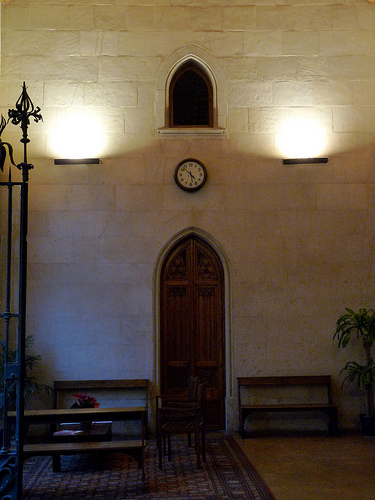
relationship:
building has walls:
[1, 1, 374, 498] [9, 4, 375, 431]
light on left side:
[39, 94, 114, 170] [3, 1, 200, 499]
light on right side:
[270, 114, 331, 161] [197, 3, 368, 496]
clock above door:
[171, 157, 215, 193] [157, 230, 229, 432]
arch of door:
[152, 223, 225, 261] [157, 230, 229, 432]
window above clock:
[159, 53, 220, 130] [171, 157, 215, 193]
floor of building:
[252, 428, 374, 498] [1, 1, 374, 498]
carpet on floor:
[3, 417, 266, 499] [252, 428, 374, 498]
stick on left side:
[10, 76, 40, 499] [3, 1, 200, 499]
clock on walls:
[171, 157, 215, 193] [9, 4, 375, 431]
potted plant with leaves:
[324, 308, 375, 441] [332, 304, 375, 396]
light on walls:
[39, 94, 114, 170] [9, 4, 375, 431]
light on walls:
[270, 114, 331, 161] [9, 4, 375, 431]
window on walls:
[159, 53, 220, 130] [9, 4, 375, 431]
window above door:
[159, 53, 220, 130] [157, 230, 229, 432]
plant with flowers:
[70, 391, 102, 430] [66, 391, 101, 408]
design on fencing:
[1, 83, 48, 180] [1, 80, 29, 499]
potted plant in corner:
[324, 308, 375, 441] [328, 2, 375, 499]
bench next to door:
[234, 372, 339, 432] [157, 230, 229, 432]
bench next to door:
[46, 375, 153, 440] [157, 230, 229, 432]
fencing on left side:
[1, 80, 29, 499] [3, 1, 200, 499]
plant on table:
[70, 391, 102, 430] [49, 409, 115, 458]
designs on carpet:
[14, 442, 238, 499] [3, 417, 266, 499]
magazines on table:
[60, 418, 110, 436] [49, 409, 115, 458]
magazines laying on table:
[60, 418, 110, 436] [49, 409, 115, 458]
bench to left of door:
[234, 372, 339, 432] [157, 230, 229, 432]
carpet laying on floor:
[3, 417, 266, 499] [252, 428, 374, 498]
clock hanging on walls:
[171, 157, 215, 193] [9, 4, 375, 431]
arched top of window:
[165, 60, 214, 90] [159, 53, 220, 130]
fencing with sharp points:
[1, 80, 29, 499] [9, 77, 54, 137]